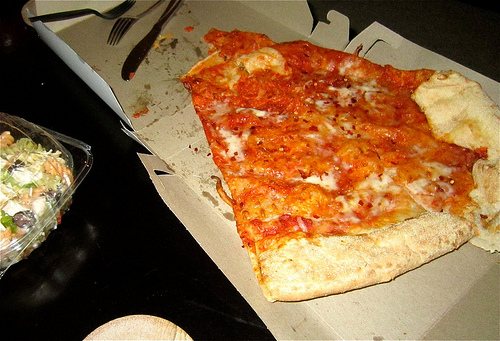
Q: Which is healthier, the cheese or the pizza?
A: The cheese is healthier than the pizza.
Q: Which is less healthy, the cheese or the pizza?
A: The pizza is less healthy than the cheese.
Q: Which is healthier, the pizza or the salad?
A: The salad is healthier than the pizza.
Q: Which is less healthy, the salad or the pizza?
A: The pizza is less healthy than the salad.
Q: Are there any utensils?
A: Yes, there are utensils.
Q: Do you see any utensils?
A: Yes, there are utensils.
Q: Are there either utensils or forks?
A: Yes, there are utensils.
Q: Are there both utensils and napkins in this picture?
A: No, there are utensils but no napkins.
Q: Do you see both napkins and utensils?
A: No, there are utensils but no napkins.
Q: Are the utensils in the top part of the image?
A: Yes, the utensils are in the top of the image.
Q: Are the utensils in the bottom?
A: No, the utensils are in the top of the image.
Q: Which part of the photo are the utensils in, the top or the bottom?
A: The utensils are in the top of the image.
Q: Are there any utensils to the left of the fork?
A: Yes, there are utensils to the left of the fork.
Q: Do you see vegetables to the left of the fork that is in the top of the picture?
A: No, there are utensils to the left of the fork.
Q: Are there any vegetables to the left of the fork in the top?
A: No, there are utensils to the left of the fork.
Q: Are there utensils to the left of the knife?
A: Yes, there are utensils to the left of the knife.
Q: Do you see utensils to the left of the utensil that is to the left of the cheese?
A: Yes, there are utensils to the left of the knife.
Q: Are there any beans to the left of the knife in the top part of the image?
A: No, there are utensils to the left of the knife.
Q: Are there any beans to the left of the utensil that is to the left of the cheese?
A: No, there are utensils to the left of the knife.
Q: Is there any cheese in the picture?
A: Yes, there is cheese.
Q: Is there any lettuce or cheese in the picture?
A: Yes, there is cheese.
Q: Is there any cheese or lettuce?
A: Yes, there is cheese.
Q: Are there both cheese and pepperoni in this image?
A: No, there is cheese but no pepperoni.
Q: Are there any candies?
A: No, there are no candies.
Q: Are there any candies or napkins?
A: No, there are no candies or napkins.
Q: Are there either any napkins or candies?
A: No, there are no candies or napkins.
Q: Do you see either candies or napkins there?
A: No, there are no candies or napkins.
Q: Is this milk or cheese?
A: This is cheese.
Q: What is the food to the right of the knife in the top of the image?
A: The food is cheese.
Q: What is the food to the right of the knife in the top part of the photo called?
A: The food is cheese.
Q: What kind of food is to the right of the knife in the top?
A: The food is cheese.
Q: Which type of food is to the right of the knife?
A: The food is cheese.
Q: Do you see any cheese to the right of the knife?
A: Yes, there is cheese to the right of the knife.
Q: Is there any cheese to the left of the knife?
A: No, the cheese is to the right of the knife.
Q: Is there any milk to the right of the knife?
A: No, there is cheese to the right of the knife.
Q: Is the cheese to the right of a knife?
A: Yes, the cheese is to the right of a knife.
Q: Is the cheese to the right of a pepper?
A: No, the cheese is to the right of a knife.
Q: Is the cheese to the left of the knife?
A: No, the cheese is to the right of the knife.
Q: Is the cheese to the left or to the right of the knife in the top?
A: The cheese is to the right of the knife.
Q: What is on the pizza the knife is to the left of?
A: The cheese is on the pizza.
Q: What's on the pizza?
A: The cheese is on the pizza.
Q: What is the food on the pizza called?
A: The food is cheese.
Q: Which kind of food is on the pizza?
A: The food is cheese.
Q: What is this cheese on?
A: The cheese is on the pizza.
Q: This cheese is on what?
A: The cheese is on the pizza.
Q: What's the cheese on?
A: The cheese is on the pizza.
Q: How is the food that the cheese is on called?
A: The food is a pizza.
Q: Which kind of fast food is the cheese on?
A: The cheese is on the pizza.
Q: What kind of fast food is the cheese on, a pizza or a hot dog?
A: The cheese is on a pizza.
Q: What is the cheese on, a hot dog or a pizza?
A: The cheese is on a pizza.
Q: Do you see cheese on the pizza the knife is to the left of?
A: Yes, there is cheese on the pizza.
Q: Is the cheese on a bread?
A: No, the cheese is on the pizza.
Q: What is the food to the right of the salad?
A: The food is cheese.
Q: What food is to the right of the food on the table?
A: The food is cheese.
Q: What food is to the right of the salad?
A: The food is cheese.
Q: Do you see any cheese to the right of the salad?
A: Yes, there is cheese to the right of the salad.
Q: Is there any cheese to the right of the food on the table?
A: Yes, there is cheese to the right of the salad.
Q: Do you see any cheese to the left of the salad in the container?
A: No, the cheese is to the right of the salad.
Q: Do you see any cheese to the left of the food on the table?
A: No, the cheese is to the right of the salad.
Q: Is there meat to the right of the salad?
A: No, there is cheese to the right of the salad.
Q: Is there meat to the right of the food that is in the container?
A: No, there is cheese to the right of the salad.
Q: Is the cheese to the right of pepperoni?
A: No, the cheese is to the right of the salad.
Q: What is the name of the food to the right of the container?
A: The food is cheese.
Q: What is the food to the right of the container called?
A: The food is cheese.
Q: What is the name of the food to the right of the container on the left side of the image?
A: The food is cheese.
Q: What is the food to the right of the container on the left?
A: The food is cheese.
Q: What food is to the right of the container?
A: The food is cheese.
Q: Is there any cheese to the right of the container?
A: Yes, there is cheese to the right of the container.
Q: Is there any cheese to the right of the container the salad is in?
A: Yes, there is cheese to the right of the container.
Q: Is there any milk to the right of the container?
A: No, there is cheese to the right of the container.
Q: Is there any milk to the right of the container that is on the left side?
A: No, there is cheese to the right of the container.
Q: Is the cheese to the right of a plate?
A: No, the cheese is to the right of the container.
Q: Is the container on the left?
A: Yes, the container is on the left of the image.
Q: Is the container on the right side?
A: No, the container is on the left of the image.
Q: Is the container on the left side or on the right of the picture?
A: The container is on the left of the image.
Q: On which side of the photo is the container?
A: The container is on the left of the image.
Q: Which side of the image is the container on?
A: The container is on the left of the image.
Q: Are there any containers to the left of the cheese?
A: Yes, there is a container to the left of the cheese.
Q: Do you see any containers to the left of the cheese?
A: Yes, there is a container to the left of the cheese.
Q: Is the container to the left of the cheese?
A: Yes, the container is to the left of the cheese.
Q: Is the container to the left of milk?
A: No, the container is to the left of the cheese.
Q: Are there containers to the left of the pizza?
A: Yes, there is a container to the left of the pizza.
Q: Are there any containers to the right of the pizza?
A: No, the container is to the left of the pizza.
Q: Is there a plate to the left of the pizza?
A: No, there is a container to the left of the pizza.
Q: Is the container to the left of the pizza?
A: Yes, the container is to the left of the pizza.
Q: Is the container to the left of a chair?
A: No, the container is to the left of the pizza.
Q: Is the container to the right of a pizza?
A: No, the container is to the left of a pizza.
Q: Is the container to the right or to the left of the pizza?
A: The container is to the left of the pizza.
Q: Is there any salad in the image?
A: Yes, there is salad.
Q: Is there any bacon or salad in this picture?
A: Yes, there is salad.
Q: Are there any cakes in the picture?
A: No, there are no cakes.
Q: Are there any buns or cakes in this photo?
A: No, there are no cakes or buns.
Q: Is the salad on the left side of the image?
A: Yes, the salad is on the left of the image.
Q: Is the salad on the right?
A: No, the salad is on the left of the image.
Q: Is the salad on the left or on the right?
A: The salad is on the left of the image.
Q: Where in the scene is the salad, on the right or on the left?
A: The salad is on the left of the image.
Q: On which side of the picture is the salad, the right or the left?
A: The salad is on the left of the image.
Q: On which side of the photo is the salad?
A: The salad is on the left of the image.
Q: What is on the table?
A: The salad is on the table.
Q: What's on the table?
A: The salad is on the table.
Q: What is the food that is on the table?
A: The food is salad.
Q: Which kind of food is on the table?
A: The food is salad.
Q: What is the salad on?
A: The salad is on the table.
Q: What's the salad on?
A: The salad is on the table.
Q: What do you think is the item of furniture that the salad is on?
A: The piece of furniture is a table.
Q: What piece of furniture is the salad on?
A: The salad is on the table.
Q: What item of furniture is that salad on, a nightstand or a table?
A: The salad is on a table.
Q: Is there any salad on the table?
A: Yes, there is salad on the table.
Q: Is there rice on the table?
A: No, there is salad on the table.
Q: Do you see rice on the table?
A: No, there is salad on the table.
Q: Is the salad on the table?
A: Yes, the salad is on the table.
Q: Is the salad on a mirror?
A: No, the salad is on the table.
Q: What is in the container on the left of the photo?
A: The salad is in the container.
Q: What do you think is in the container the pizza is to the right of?
A: The salad is in the container.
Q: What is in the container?
A: The salad is in the container.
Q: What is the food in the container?
A: The food is salad.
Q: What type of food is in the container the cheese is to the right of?
A: The food is salad.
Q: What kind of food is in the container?
A: The food is salad.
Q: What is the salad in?
A: The salad is in the container.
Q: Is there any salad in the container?
A: Yes, there is salad in the container.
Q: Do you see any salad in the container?
A: Yes, there is salad in the container.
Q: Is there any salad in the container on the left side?
A: Yes, there is salad in the container.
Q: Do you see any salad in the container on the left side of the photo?
A: Yes, there is salad in the container.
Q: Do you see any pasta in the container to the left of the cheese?
A: No, there is salad in the container.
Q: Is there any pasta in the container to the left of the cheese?
A: No, there is salad in the container.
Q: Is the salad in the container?
A: Yes, the salad is in the container.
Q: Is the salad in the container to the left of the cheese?
A: Yes, the salad is in the container.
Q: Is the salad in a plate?
A: No, the salad is in the container.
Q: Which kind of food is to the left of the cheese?
A: The food is salad.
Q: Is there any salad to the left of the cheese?
A: Yes, there is salad to the left of the cheese.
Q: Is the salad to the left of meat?
A: No, the salad is to the left of the cheese.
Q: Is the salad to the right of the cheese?
A: No, the salad is to the left of the cheese.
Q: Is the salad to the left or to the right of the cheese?
A: The salad is to the left of the cheese.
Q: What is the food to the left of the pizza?
A: The food is salad.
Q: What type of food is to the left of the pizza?
A: The food is salad.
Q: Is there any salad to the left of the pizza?
A: Yes, there is salad to the left of the pizza.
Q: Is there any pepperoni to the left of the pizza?
A: No, there is salad to the left of the pizza.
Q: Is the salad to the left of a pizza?
A: Yes, the salad is to the left of a pizza.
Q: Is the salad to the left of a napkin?
A: No, the salad is to the left of a pizza.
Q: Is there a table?
A: Yes, there is a table.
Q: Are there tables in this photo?
A: Yes, there is a table.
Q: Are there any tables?
A: Yes, there is a table.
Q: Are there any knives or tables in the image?
A: Yes, there is a table.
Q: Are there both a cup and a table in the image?
A: No, there is a table but no cups.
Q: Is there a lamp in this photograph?
A: No, there are no lamps.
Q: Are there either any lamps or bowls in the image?
A: No, there are no lamps or bowls.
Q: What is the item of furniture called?
A: The piece of furniture is a table.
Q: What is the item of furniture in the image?
A: The piece of furniture is a table.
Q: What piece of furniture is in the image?
A: The piece of furniture is a table.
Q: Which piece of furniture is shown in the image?
A: The piece of furniture is a table.